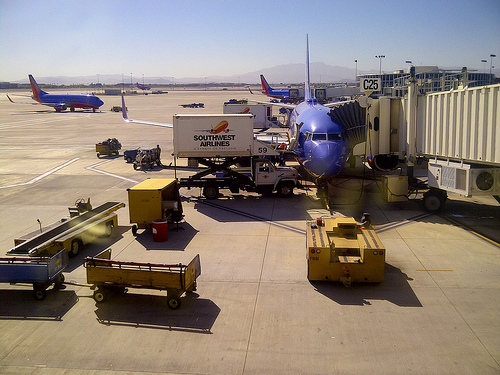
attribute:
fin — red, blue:
[25, 71, 47, 94]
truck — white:
[168, 109, 292, 166]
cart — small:
[0, 252, 71, 297]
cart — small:
[81, 248, 202, 310]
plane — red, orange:
[194, 117, 238, 136]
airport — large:
[12, 91, 482, 373]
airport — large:
[2, 1, 498, 372]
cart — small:
[93, 130, 119, 160]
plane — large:
[223, 47, 395, 195]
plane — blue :
[23, 63, 124, 126]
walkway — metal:
[367, 77, 484, 211]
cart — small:
[0, 201, 128, 290]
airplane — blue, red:
[12, 72, 130, 134]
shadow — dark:
[93, 290, 222, 335]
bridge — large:
[322, 65, 499, 217]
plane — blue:
[25, 74, 103, 114]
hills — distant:
[0, 51, 471, 83]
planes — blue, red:
[24, 72, 104, 109]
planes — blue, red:
[259, 72, 289, 101]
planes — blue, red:
[287, 30, 346, 181]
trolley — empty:
[84, 237, 214, 315]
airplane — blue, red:
[135, 81, 152, 89]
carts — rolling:
[92, 134, 174, 191]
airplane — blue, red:
[8, 71, 105, 116]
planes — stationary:
[284, 65, 404, 177]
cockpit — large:
[301, 124, 343, 160]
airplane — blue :
[9, 68, 114, 125]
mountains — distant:
[322, 57, 359, 79]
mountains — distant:
[261, 60, 298, 82]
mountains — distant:
[116, 63, 237, 90]